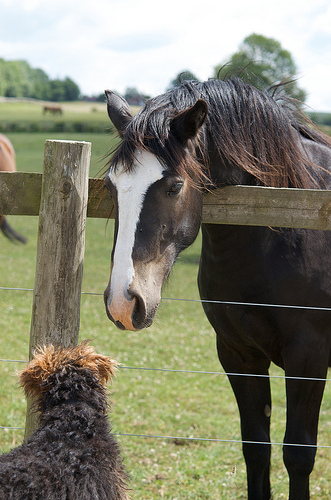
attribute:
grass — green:
[130, 365, 224, 452]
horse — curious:
[65, 59, 329, 368]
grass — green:
[1, 131, 330, 498]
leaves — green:
[212, 33, 305, 105]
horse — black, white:
[90, 76, 327, 486]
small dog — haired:
[2, 336, 153, 499]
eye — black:
[169, 174, 183, 193]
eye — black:
[103, 180, 114, 205]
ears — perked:
[101, 83, 213, 142]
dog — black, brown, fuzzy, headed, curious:
[1, 341, 136, 498]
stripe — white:
[107, 145, 167, 300]